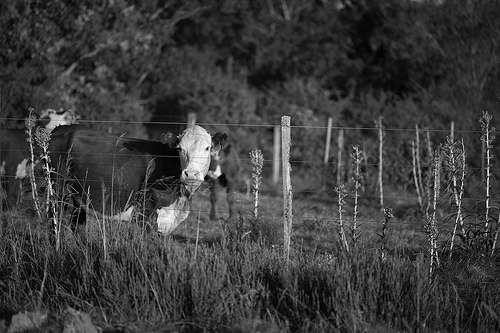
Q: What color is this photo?
A: Black and white.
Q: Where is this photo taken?
A: A field.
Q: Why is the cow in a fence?
A: So it doesn't get out.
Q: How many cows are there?
A: One.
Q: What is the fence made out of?
A: Wire.